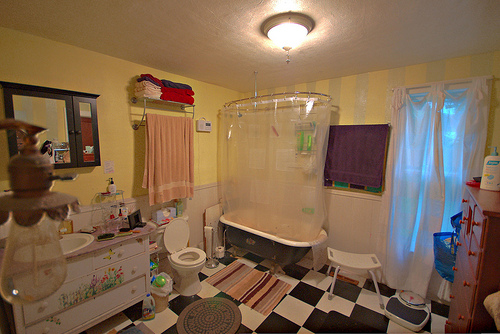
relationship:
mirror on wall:
[21, 72, 96, 164] [3, 48, 142, 203]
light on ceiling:
[278, 25, 307, 55] [206, 20, 351, 114]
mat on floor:
[205, 258, 292, 316] [150, 250, 322, 334]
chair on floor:
[325, 247, 387, 310] [150, 250, 322, 334]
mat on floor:
[230, 271, 261, 306] [150, 250, 322, 334]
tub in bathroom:
[194, 167, 361, 281] [53, 44, 472, 334]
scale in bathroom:
[379, 276, 436, 330] [53, 44, 472, 334]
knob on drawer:
[122, 259, 146, 283] [95, 243, 154, 313]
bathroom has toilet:
[14, 33, 466, 332] [158, 210, 213, 273]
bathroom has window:
[14, 33, 466, 332] [373, 109, 463, 194]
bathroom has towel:
[14, 33, 466, 332] [159, 137, 206, 170]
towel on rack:
[159, 137, 206, 170] [129, 101, 196, 144]